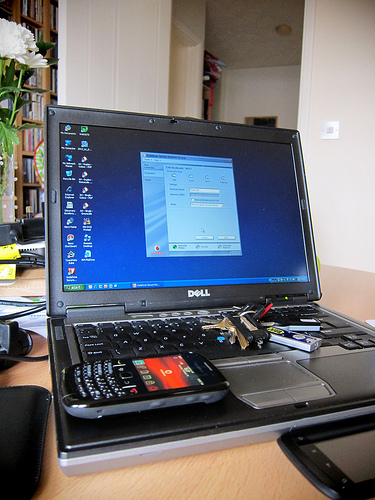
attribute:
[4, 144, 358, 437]
laptop — open, dell, behind, top, black, computer, grey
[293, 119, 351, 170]
switch — light, white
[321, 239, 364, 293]
floor — white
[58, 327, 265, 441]
phone — cell, black, smart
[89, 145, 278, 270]
screen — blue, computer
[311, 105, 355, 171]
stat — thermo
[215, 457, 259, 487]
table — wood, everything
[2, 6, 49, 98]
flower — white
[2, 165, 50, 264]
vase — glass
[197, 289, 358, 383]
key — sitting, group, chain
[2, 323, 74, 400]
cord — sitting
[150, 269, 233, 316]
computer — name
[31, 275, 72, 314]
paper — some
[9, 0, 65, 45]
shelf — book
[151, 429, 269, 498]
desk — wooden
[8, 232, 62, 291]
wire — group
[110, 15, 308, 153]
office — interior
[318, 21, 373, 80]
wall — beige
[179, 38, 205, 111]
trim — white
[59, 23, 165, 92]
door — white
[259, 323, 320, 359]
chain — key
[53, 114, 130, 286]
icon — desktop